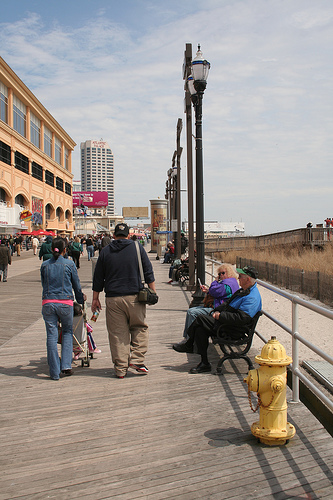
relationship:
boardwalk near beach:
[2, 246, 332, 499] [206, 223, 332, 310]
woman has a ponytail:
[39, 238, 86, 379] [55, 246, 61, 258]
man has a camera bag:
[93, 224, 155, 376] [139, 288, 160, 306]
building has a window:
[81, 140, 114, 216] [46, 123, 53, 162]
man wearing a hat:
[172, 264, 262, 372] [237, 261, 256, 280]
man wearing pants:
[172, 264, 262, 372] [191, 310, 256, 356]